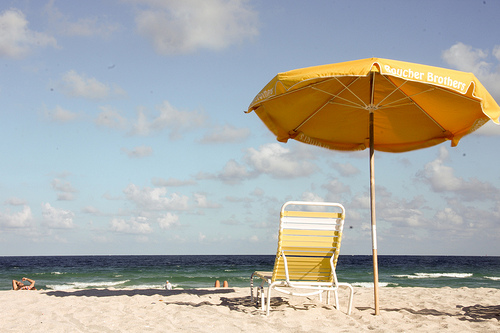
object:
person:
[10, 274, 39, 293]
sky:
[169, 145, 275, 248]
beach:
[384, 283, 498, 324]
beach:
[81, 314, 333, 329]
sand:
[187, 308, 197, 327]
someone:
[161, 278, 176, 293]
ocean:
[76, 259, 247, 272]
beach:
[133, 294, 164, 302]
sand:
[339, 314, 431, 329]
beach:
[19, 291, 469, 330]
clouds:
[50, 171, 87, 196]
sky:
[10, 10, 314, 187]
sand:
[46, 298, 225, 328]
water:
[65, 257, 220, 276]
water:
[121, 253, 216, 266]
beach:
[160, 305, 415, 330]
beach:
[8, 295, 238, 327]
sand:
[127, 310, 170, 326]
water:
[43, 256, 222, 277]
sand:
[29, 298, 150, 330]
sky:
[24, 95, 244, 190]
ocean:
[22, 251, 262, 291]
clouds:
[98, 212, 147, 236]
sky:
[13, 114, 258, 223]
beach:
[6, 294, 149, 330]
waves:
[30, 254, 235, 292]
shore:
[3, 283, 242, 330]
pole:
[364, 114, 382, 313]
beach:
[5, 283, 498, 323]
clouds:
[52, 66, 118, 102]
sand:
[19, 278, 279, 328]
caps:
[390, 270, 468, 278]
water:
[5, 252, 496, 287]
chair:
[244, 200, 355, 313]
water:
[6, 255, 498, 265]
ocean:
[0, 258, 499, 296]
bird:
[159, 279, 175, 289]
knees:
[224, 277, 228, 282]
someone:
[213, 279, 228, 286]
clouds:
[40, 206, 79, 230]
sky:
[3, 9, 492, 255]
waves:
[395, 265, 477, 285]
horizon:
[7, 239, 490, 260]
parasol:
[244, 54, 499, 153]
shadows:
[45, 286, 235, 295]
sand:
[6, 290, 498, 330]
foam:
[483, 272, 498, 279]